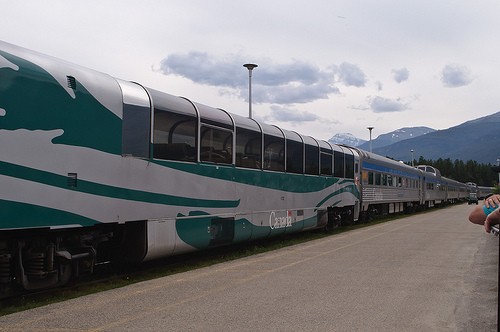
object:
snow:
[345, 134, 349, 136]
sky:
[4, 1, 498, 144]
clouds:
[442, 63, 471, 88]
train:
[0, 40, 491, 293]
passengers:
[471, 193, 499, 236]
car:
[1, 42, 356, 291]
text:
[269, 210, 292, 229]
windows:
[344, 154, 353, 179]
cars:
[358, 147, 423, 214]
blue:
[363, 162, 368, 167]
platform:
[14, 231, 500, 329]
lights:
[367, 126, 374, 130]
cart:
[467, 192, 478, 205]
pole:
[249, 70, 253, 117]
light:
[243, 63, 258, 69]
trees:
[457, 158, 467, 182]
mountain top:
[332, 132, 356, 139]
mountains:
[396, 111, 500, 146]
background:
[1, 7, 497, 135]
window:
[197, 123, 233, 164]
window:
[319, 152, 335, 176]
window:
[262, 133, 285, 174]